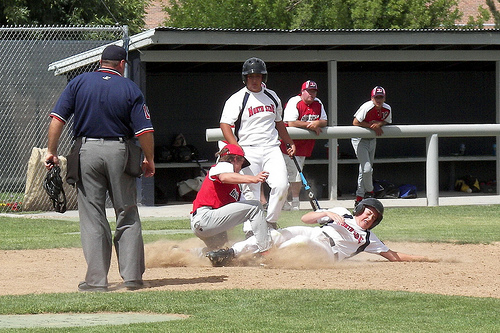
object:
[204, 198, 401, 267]
baseball player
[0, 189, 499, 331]
ground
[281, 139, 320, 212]
baseball bat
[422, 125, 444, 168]
ground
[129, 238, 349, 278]
dust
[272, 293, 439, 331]
grass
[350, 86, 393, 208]
player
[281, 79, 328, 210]
player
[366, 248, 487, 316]
sand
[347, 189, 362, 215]
ground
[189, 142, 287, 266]
player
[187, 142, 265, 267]
uniform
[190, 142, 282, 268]
catcher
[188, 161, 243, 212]
shirt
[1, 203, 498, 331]
grass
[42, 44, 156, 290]
umpire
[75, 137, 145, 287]
pants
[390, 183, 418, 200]
bag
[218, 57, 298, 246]
player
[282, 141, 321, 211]
bat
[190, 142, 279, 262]
catcher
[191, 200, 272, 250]
pants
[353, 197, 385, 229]
helmet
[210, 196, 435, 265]
player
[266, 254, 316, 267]
base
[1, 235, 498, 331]
dirt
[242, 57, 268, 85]
helmet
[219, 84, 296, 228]
person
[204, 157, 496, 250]
sideline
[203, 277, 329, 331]
base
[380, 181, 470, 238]
ground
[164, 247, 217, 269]
home plate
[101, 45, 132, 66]
cap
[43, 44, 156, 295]
umpire